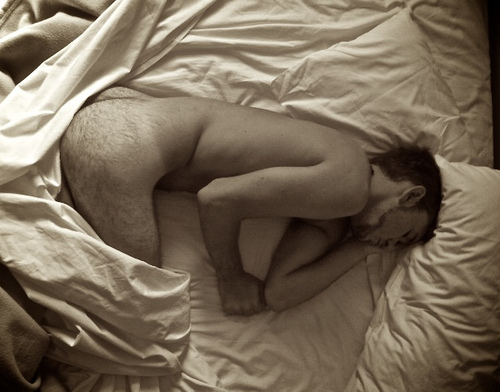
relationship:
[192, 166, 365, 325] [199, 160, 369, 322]
arm bent at elbow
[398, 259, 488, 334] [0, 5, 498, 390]
pillow on bed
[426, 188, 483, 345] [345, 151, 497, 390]
wrinkles on pillow case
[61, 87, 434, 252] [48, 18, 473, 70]
naked laying on sheets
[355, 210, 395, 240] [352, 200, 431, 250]
beard on face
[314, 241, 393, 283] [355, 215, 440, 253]
hand under face